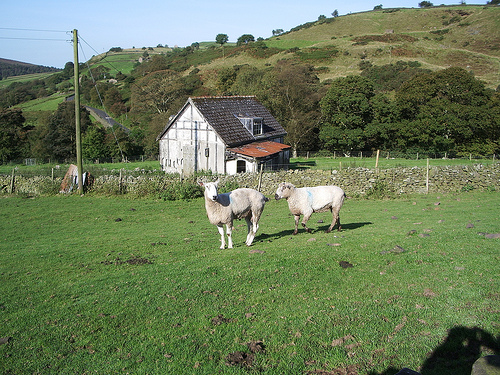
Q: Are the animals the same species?
A: Yes, all the animals are sheep.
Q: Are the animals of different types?
A: No, all the animals are sheep.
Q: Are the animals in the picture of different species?
A: No, all the animals are sheep.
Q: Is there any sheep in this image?
A: Yes, there is a sheep.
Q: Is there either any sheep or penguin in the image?
A: Yes, there is a sheep.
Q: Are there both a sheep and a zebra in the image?
A: No, there is a sheep but no zebras.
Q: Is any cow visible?
A: No, there are no cows.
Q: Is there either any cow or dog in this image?
A: No, there are no cows or dogs.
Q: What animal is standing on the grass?
A: The sheep is standing on the grass.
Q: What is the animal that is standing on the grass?
A: The animal is a sheep.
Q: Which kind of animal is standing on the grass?
A: The animal is a sheep.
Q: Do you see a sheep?
A: Yes, there is a sheep.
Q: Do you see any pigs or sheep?
A: Yes, there is a sheep.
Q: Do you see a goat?
A: No, there are no goats.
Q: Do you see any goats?
A: No, there are no goats.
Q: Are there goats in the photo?
A: No, there are no goats.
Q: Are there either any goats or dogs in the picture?
A: No, there are no goats or dogs.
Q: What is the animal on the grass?
A: The animal is a sheep.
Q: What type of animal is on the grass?
A: The animal is a sheep.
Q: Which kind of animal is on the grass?
A: The animal is a sheep.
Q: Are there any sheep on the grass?
A: Yes, there is a sheep on the grass.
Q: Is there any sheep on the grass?
A: Yes, there is a sheep on the grass.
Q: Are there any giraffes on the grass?
A: No, there is a sheep on the grass.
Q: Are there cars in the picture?
A: No, there are no cars.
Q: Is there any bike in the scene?
A: No, there are no bikes.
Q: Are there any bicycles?
A: No, there are no bicycles.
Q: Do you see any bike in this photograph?
A: No, there are no bikes.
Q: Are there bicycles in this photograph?
A: No, there are no bicycles.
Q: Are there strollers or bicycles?
A: No, there are no bicycles or strollers.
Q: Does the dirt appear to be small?
A: Yes, the dirt is small.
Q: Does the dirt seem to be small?
A: Yes, the dirt is small.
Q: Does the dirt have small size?
A: Yes, the dirt is small.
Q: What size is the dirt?
A: The dirt is small.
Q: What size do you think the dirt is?
A: The dirt is small.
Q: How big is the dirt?
A: The dirt is small.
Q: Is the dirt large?
A: No, the dirt is small.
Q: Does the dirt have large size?
A: No, the dirt is small.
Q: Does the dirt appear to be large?
A: No, the dirt is small.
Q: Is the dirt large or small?
A: The dirt is small.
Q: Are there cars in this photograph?
A: No, there are no cars.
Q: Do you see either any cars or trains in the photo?
A: No, there are no cars or trains.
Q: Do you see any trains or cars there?
A: No, there are no cars or trains.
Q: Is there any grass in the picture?
A: Yes, there is grass.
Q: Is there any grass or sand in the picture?
A: Yes, there is grass.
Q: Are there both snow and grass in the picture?
A: No, there is grass but no snow.